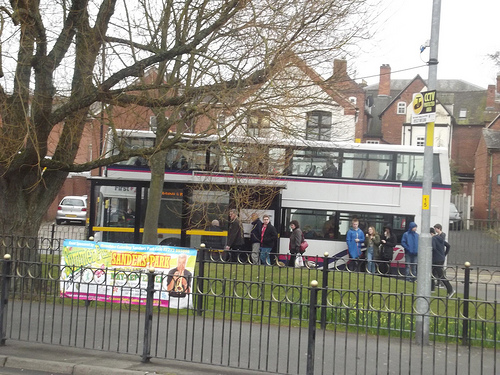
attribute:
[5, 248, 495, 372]
fence — metal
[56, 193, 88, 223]
car — silver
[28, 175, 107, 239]
coupe — small, silver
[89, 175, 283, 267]
bus stop — glass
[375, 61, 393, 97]
chimney — brick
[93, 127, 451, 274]
bus — white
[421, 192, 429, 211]
sticker — yellow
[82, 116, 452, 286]
bus — double decker, white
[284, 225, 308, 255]
coat — brown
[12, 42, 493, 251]
building — brick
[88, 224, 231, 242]
stripe — yellow